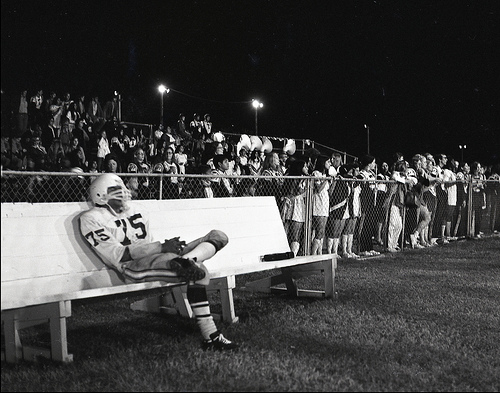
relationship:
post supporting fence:
[301, 176, 316, 256] [12, 151, 499, 256]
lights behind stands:
[157, 80, 169, 120] [1, 114, 498, 259]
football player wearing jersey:
[79, 172, 241, 352] [76, 206, 155, 275]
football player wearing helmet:
[79, 172, 241, 352] [86, 172, 133, 208]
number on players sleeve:
[81, 228, 108, 247] [76, 212, 131, 269]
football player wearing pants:
[79, 172, 241, 352] [120, 227, 228, 283]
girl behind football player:
[280, 157, 310, 257] [79, 172, 241, 352]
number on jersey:
[99, 210, 154, 256] [76, 206, 155, 275]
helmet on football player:
[88, 172, 133, 205] [79, 172, 241, 352]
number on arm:
[84, 228, 111, 247] [70, 206, 163, 264]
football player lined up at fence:
[79, 172, 241, 352] [0, 170, 497, 260]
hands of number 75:
[162, 233, 187, 253] [78, 171, 236, 351]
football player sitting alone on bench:
[79, 172, 241, 352] [7, 174, 345, 369]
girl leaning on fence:
[284, 157, 314, 256] [0, 170, 497, 260]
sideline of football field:
[2, 189, 490, 283] [0, 234, 499, 391]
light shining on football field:
[148, 78, 172, 100] [0, 234, 499, 391]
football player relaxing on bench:
[79, 172, 241, 352] [5, 197, 123, 339]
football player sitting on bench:
[79, 172, 241, 352] [5, 197, 123, 339]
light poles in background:
[153, 80, 170, 132] [7, 10, 462, 154]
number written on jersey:
[115, 212, 148, 246] [71, 201, 168, 256]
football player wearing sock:
[79, 172, 241, 352] [194, 294, 217, 333]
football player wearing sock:
[79, 172, 241, 352] [190, 235, 226, 270]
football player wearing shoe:
[79, 172, 241, 352] [167, 256, 205, 283]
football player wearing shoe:
[79, 172, 241, 352] [200, 330, 239, 349]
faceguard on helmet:
[108, 186, 138, 205] [65, 157, 150, 204]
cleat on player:
[173, 257, 203, 281] [75, 167, 265, 373]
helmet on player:
[88, 172, 133, 205] [78, 149, 259, 358]